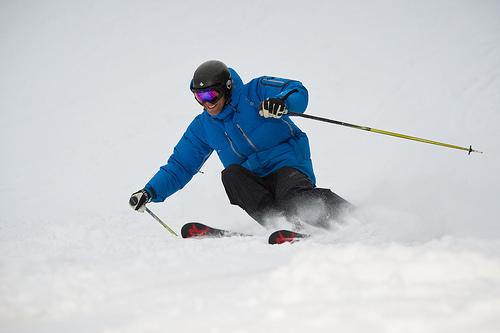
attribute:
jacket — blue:
[143, 64, 317, 206]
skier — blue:
[126, 60, 357, 240]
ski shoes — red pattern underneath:
[170, 210, 326, 244]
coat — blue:
[127, 61, 318, 194]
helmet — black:
[185, 58, 237, 117]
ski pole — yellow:
[260, 99, 482, 156]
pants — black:
[212, 154, 374, 228]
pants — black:
[205, 158, 381, 232]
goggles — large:
[185, 85, 228, 103]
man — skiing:
[118, 53, 386, 229]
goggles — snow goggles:
[181, 77, 230, 108]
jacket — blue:
[132, 68, 324, 188]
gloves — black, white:
[102, 80, 302, 217]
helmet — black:
[179, 51, 237, 117]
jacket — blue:
[133, 69, 318, 199]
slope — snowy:
[4, 6, 464, 310]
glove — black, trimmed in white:
[250, 89, 293, 125]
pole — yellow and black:
[311, 135, 480, 154]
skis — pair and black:
[121, 115, 476, 265]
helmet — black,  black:
[179, 55, 233, 106]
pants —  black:
[246, 165, 304, 252]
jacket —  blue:
[170, 80, 311, 170]